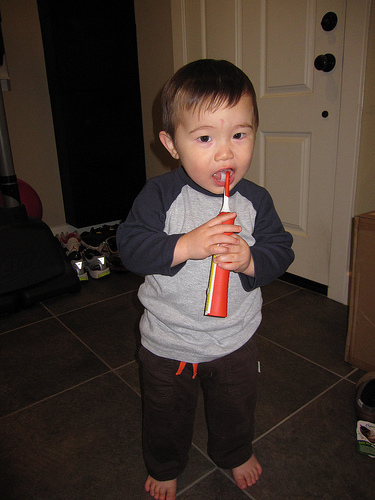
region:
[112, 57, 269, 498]
a small toddler brushing his teeth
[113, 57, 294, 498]
a small boy wearing a blue and gray shirt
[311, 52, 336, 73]
a black door knob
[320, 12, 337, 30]
a black door lock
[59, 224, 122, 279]
a pile of shoes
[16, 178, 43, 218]
the side of an orange ball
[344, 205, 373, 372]
a small cardboard box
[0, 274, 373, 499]
dark grey tile floors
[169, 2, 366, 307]
a white door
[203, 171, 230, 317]
an orange and white electric toothbrush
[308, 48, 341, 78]
metal doorknob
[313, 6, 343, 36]
metal deadbolt on door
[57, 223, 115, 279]
tennis shoes on floor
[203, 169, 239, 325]
orange and white electric toothbrush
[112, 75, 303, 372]
boy holding electric toothbrush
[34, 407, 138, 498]
dark floor tiles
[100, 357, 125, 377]
white grout between floor tiles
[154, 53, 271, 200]
boy with brown hair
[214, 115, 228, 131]
red scar on forehead of boy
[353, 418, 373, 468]
green and white magazine laying on floor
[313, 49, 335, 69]
The black door knob on the door behind the child.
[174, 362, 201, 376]
The orange strings on the child's pants.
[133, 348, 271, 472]
The brown pants the child is wearing.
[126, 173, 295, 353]
The gray and black shirt the child is wearing.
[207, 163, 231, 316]
The orange and white toothbrush in the child's hands.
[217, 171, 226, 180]
The white bristles of the toothbrush in the child's mouth.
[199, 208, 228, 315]
The orange and yellow handle of the toothbrush.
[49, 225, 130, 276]
The lot of sneakers behind the child.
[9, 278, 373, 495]
The brown tiles on the floor the child is standing on.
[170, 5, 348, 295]
The white door behind the child.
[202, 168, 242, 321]
a long orange toothbrush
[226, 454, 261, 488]
a child's bare foot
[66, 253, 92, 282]
a glow in the dark shoe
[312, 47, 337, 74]
a door knob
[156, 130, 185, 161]
the ear of a boy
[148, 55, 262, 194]
the head of a boy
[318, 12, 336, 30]
a deadbolt lock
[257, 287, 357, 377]
a piece of floor tile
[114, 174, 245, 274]
the arm of a boy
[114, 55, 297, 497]
a very young child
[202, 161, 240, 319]
orange toothbrush being held by the child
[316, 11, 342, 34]
a black lock on the door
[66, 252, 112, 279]
grey, white, and green shoes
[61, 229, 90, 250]
red and white shoes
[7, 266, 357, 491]
a dark tiled floor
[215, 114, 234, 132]
a scar on the child's face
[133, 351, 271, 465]
black pants worn by the child